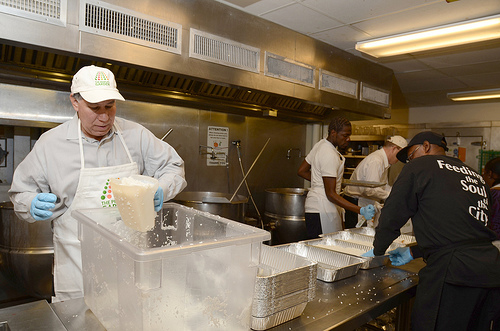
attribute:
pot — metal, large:
[262, 183, 313, 225]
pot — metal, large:
[169, 188, 252, 226]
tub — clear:
[77, 194, 301, 311]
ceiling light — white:
[354, 11, 499, 62]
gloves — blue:
[27, 181, 169, 226]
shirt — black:
[371, 155, 498, 255]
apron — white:
[48, 120, 150, 300]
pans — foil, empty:
[239, 237, 340, 329]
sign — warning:
[204, 123, 231, 165]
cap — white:
[69, 59, 124, 106]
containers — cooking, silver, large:
[264, 186, 306, 236]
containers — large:
[174, 188, 248, 222]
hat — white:
[44, 60, 125, 109]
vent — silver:
[356, 81, 391, 107]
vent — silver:
[319, 67, 358, 102]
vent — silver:
[265, 51, 318, 96]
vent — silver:
[184, 21, 261, 78]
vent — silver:
[82, 0, 188, 54]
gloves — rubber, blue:
[13, 174, 68, 236]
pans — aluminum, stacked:
[252, 243, 319, 329]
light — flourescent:
[358, 31, 438, 60]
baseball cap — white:
[66, 63, 127, 105]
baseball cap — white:
[385, 130, 412, 155]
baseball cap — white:
[392, 126, 452, 157]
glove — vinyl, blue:
[20, 191, 58, 224]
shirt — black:
[372, 154, 492, 263]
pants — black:
[410, 241, 499, 330]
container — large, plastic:
[74, 188, 274, 329]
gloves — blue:
[21, 191, 168, 218]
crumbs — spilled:
[331, 279, 394, 311]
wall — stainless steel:
[188, 119, 290, 191]